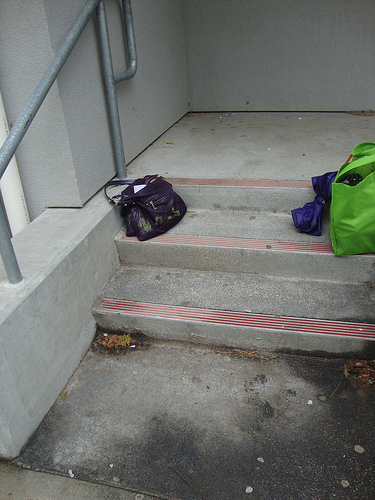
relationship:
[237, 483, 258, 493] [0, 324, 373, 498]
white spot on ground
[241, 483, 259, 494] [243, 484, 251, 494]
spot on ground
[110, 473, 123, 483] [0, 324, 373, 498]
spot on ground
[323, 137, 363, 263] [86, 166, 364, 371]
tote bag on stairs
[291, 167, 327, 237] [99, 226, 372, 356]
blue umbrella on stairs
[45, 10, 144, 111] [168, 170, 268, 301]
railings next to stairs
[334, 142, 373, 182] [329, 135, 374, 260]
green handles on tote bag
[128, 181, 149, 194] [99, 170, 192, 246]
paper in bag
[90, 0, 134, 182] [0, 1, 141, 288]
pole under railing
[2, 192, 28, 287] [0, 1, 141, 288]
pole under railing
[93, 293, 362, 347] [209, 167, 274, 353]
treads on stairs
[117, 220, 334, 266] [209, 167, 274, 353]
treads on stairs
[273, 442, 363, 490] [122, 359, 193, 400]
stain on cement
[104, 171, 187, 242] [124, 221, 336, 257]
bag on stairs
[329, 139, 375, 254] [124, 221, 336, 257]
bag on stairs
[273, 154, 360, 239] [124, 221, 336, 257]
umbrella on stairs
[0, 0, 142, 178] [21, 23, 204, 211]
railings next to wall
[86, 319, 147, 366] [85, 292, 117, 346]
debris laying in corner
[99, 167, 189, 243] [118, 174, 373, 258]
purse laying on stairs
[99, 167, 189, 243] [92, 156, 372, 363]
purse sitting on steps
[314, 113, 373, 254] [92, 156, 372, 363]
bag sitting on steps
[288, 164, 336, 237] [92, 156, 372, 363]
umbrella sitting on steps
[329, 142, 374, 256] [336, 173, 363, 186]
item inside of bag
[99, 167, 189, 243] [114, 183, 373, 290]
purse sitting on step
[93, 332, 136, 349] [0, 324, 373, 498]
debris laying on ground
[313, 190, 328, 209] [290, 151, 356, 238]
tie around middle of umbrella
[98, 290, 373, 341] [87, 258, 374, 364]
marker on step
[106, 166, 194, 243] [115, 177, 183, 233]
bag has leather